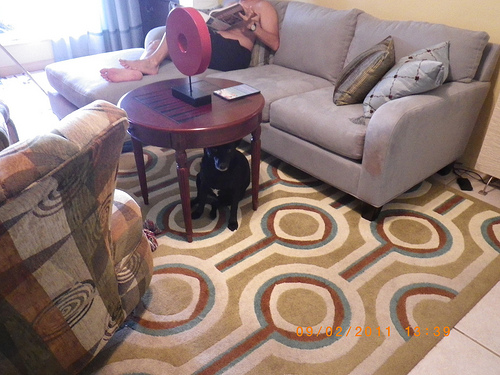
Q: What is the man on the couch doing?
A: Reading a book.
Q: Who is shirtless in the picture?
A: The man on the couch.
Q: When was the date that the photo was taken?
A: 09/02/2011.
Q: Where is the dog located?
A: Under the table.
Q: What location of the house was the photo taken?
A: Living room.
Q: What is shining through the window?
A: Sunlight.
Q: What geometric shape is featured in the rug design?
A: Circle.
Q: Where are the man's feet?
A: On the couch.